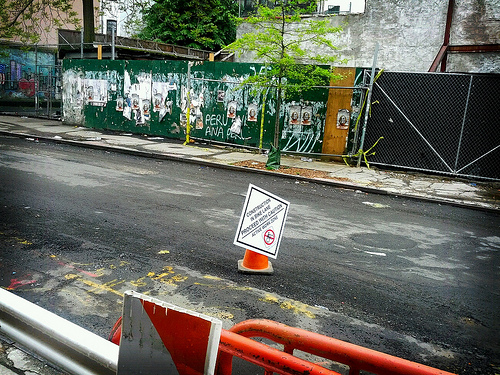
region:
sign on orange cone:
[226, 183, 287, 283]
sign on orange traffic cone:
[226, 177, 296, 274]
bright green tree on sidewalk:
[218, 39, 342, 165]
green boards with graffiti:
[59, 58, 369, 161]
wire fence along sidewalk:
[193, 67, 497, 169]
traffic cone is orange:
[222, 247, 277, 279]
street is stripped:
[4, 124, 492, 371]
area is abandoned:
[4, 8, 494, 195]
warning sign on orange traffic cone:
[209, 183, 289, 278]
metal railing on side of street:
[3, 277, 120, 373]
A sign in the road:
[228, 174, 297, 276]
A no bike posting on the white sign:
[261, 221, 277, 246]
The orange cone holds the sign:
[234, 253, 274, 276]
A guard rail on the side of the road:
[1, 290, 118, 374]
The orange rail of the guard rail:
[217, 317, 457, 372]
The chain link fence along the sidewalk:
[383, 66, 499, 179]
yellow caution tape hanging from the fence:
[352, 67, 384, 174]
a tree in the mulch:
[225, 3, 345, 180]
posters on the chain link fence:
[221, 101, 268, 123]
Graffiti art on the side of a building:
[1, 47, 58, 102]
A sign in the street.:
[234, 175, 294, 269]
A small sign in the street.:
[218, 168, 300, 267]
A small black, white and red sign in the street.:
[218, 168, 283, 291]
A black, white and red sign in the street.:
[225, 170, 315, 270]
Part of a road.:
[48, 149, 177, 217]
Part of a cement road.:
[45, 153, 170, 218]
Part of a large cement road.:
[71, 159, 156, 219]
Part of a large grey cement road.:
[66, 157, 194, 220]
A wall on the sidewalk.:
[68, 57, 366, 159]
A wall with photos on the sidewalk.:
[57, 59, 377, 164]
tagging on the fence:
[202, 111, 232, 138]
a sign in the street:
[232, 188, 312, 255]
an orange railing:
[260, 305, 339, 364]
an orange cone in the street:
[233, 246, 276, 278]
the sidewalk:
[337, 158, 393, 185]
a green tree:
[234, 30, 324, 169]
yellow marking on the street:
[35, 255, 122, 302]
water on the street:
[401, 230, 493, 290]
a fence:
[18, 68, 55, 118]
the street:
[32, 166, 142, 235]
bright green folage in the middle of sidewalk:
[218, 5, 353, 176]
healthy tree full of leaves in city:
[137, 1, 237, 51]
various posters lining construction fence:
[60, 60, 257, 150]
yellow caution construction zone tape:
[332, 70, 373, 167]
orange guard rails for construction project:
[220, 315, 450, 370]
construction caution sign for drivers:
[222, 185, 287, 277]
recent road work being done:
[280, 245, 475, 355]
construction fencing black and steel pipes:
[352, 60, 487, 187]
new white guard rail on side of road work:
[0, 291, 115, 368]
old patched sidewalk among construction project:
[323, 163, 489, 208]